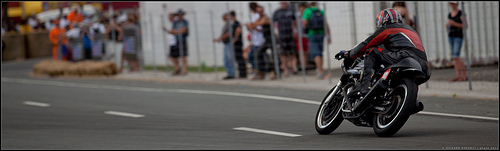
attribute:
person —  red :
[340, 7, 434, 99]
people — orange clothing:
[46, 9, 109, 69]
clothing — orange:
[46, 4, 95, 64]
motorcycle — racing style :
[308, 45, 445, 128]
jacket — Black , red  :
[377, 25, 418, 57]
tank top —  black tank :
[434, 8, 474, 43]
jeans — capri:
[445, 31, 463, 58]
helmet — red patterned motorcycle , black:
[369, 9, 412, 24]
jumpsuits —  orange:
[49, 21, 71, 57]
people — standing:
[163, 6, 190, 81]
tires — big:
[373, 89, 418, 130]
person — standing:
[233, 20, 285, 71]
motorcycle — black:
[311, 47, 426, 137]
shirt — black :
[449, 9, 465, 36]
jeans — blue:
[449, 35, 461, 58]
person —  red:
[268, 0, 300, 77]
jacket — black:
[343, 22, 424, 60]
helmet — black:
[372, 7, 402, 25]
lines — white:
[66, 71, 237, 143]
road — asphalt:
[4, 71, 494, 149]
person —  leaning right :
[364, 5, 433, 75]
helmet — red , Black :
[377, 9, 409, 24]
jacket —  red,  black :
[356, 27, 442, 71]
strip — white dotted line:
[102, 100, 302, 149]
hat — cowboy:
[176, 7, 196, 23]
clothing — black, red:
[361, 22, 426, 62]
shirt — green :
[302, 7, 326, 45]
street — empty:
[6, 80, 478, 149]